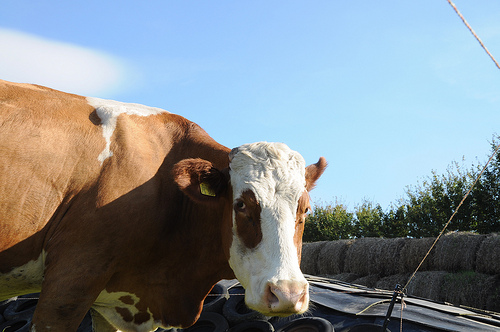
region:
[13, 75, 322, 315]
brown and white cow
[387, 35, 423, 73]
white clouds in blue sky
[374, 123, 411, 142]
white clouds in blue sky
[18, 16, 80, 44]
white clouds in blue sky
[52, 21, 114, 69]
white clouds in blue sky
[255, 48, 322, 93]
white clouds in blue sky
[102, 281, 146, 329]
brown and white spots on cow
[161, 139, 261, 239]
brown ear on cow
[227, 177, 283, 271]
brown circle around cow eye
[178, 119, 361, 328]
cows head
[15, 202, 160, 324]
front upper leg on cow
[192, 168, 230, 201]
yellow auction tag in cows ear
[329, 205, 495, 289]
round bails of hay stacks in row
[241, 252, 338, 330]
cows pink nose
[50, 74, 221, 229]
white markings on back on brown cow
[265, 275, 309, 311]
The nose of the cow.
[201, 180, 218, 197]
A yellow tag in the cow's ear.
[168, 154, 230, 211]
The cow's brown ear.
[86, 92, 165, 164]
A white spot on the cow.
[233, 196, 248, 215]
The cow's eye.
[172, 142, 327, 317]
The head of the cow.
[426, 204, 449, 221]
Part of a green bush.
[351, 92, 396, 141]
Part of the blue sky.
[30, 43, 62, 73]
Part of a white cloud.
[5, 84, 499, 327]
a brown and cow has a yellow tag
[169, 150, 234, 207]
the yellow tag is in the cow's ear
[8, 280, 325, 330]
old tires are behind the cow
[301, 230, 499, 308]
bales of hay are near the cow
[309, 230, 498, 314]
the bales are stacked on top of each other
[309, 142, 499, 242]
a green hedge is behind the hay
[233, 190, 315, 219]
the cow has black eyes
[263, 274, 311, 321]
the cow has a light pink nose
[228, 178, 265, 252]
a brown furry spot is around the eye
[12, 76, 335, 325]
white and brown cow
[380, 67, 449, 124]
white clouds in blue sky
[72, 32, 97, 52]
white clouds in blue sky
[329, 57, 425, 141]
white clouds in blue sky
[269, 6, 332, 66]
white clouds in blue sky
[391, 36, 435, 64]
white clouds in blue sky